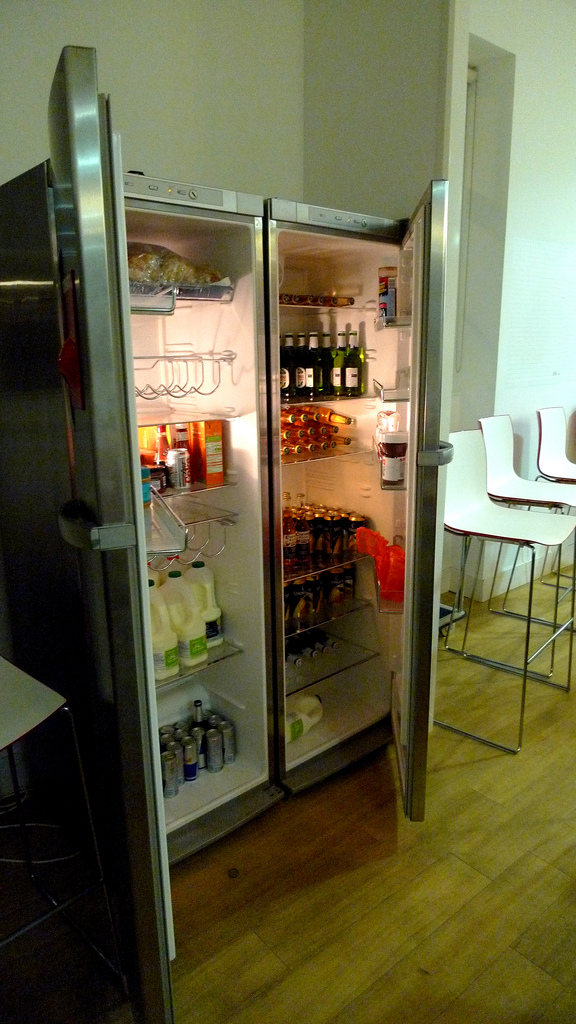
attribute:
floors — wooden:
[177, 741, 575, 1021]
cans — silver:
[157, 705, 240, 807]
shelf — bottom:
[156, 723, 265, 825]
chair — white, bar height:
[434, 428, 574, 757]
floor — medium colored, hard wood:
[117, 565, 573, 1021]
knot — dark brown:
[228, 867, 237, 880]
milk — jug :
[186, 558, 225, 646]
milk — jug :
[285, 690, 323, 745]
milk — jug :
[145, 579, 181, 681]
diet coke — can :
[166, 447, 189, 491]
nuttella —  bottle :
[377, 432, 405, 488]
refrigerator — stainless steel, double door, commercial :
[2, 45, 450, 1022]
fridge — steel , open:
[3, 45, 447, 1020]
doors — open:
[41, 40, 460, 1021]